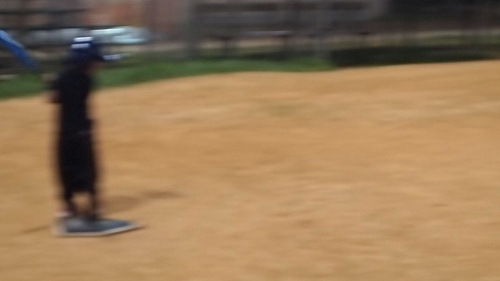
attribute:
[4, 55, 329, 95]
grass — green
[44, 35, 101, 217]
kid — young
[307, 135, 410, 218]
dirt — red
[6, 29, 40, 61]
bat — in air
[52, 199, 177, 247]
plate — home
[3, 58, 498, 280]
dirt — brown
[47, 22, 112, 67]
helmet — blue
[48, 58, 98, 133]
shirt — black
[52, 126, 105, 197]
shorts — pair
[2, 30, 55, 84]
bat — blue, blurry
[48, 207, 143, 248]
base plate — blue, white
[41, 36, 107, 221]
person — leg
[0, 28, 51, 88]
bat — blue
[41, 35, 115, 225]
batter — blurred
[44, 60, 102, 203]
clothing — black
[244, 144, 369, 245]
ground — dirt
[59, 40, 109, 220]
person — head